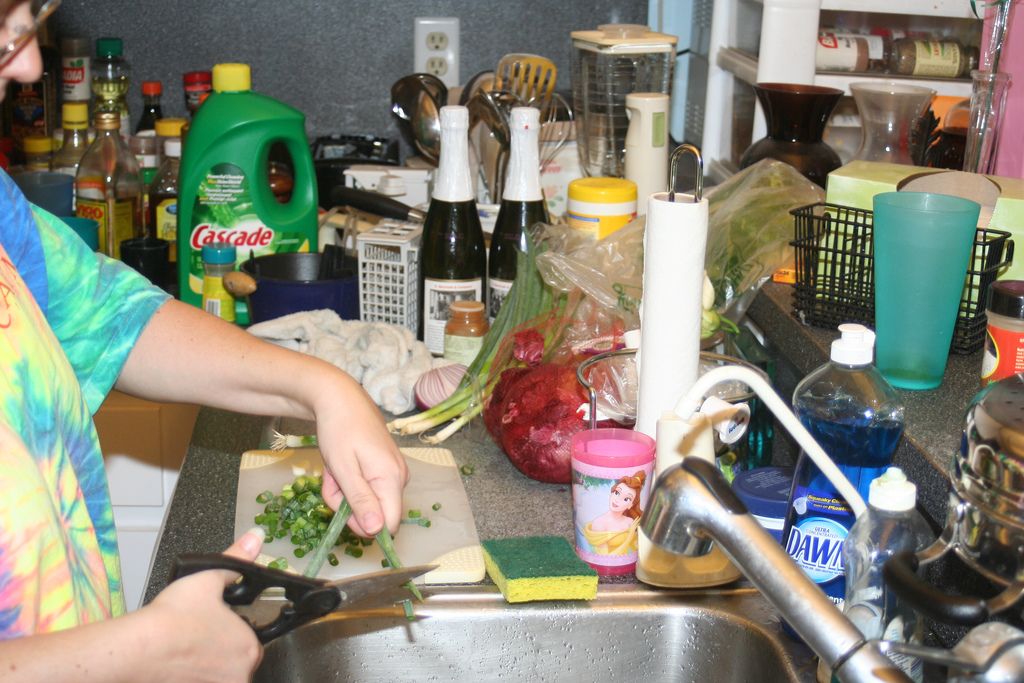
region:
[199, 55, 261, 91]
Lid on a bottle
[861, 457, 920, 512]
Lid on a bottle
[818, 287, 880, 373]
Lid on a bottle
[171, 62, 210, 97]
Lid on a bottle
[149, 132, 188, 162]
Lid on a bottle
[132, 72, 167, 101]
Lid on a bottle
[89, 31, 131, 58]
Lid on a bottle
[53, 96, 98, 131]
Lid on a bottle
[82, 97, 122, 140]
Lid on a bottle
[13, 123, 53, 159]
Lid on a bottle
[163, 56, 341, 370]
a green plastic container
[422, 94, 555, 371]
several wine bottles next to each other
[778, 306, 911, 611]
a bottle of dish washing liquid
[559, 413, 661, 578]
a pink cup with a princess design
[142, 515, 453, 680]
a hand holding a pair of kitchen sheers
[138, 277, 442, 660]
a person cutting some vegetables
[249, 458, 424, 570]
chopped vegetables on a chopping board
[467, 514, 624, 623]
a dish scrub pad with foam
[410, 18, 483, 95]
a wall outlet with 2 sockets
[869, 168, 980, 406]
a green plastic cup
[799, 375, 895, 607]
liquid is blue in color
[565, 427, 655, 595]
cup is pink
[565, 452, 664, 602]
cup has woman on it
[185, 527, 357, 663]
scissors handle is black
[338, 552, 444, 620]
scissor blades are silver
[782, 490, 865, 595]
logo on bottle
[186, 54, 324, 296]
bottle is green in color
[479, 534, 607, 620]
sponge is yellow and green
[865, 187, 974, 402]
cup is blue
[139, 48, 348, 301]
green container on the counter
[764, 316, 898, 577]
dishwasher on the sink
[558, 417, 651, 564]
cup on the counter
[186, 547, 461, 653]
woman holding black scissor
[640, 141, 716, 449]
paper towel on the counter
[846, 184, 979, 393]
green cup on the counter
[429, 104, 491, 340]
wine bottle on the counter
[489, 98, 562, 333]
wine bottle on the counter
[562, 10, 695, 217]
white blender on the counter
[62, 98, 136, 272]
oil on the counter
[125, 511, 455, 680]
hand holding a scissor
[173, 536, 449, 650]
the scissor is black and gray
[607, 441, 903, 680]
the faucet is color silver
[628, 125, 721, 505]
kitchen paper is white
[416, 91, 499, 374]
a bottle of wine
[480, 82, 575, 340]
a bottle of wine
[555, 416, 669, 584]
the cup is pink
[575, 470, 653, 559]
a fairy on a cup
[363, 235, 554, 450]
onions on a table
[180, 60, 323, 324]
Green bottle of dishwasher liquid.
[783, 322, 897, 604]
Blue bottle of dish washing soap on the sink.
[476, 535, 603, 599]
Green and yellow sponge on the sink.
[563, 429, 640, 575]
Pink cup with a princess on the sink.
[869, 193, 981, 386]
Large blue cup behind the sink.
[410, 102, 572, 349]
Two champagne bottles near a yellow canister.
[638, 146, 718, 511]
Paper towels on a metal pole.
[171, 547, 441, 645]
Scissors being used to cut.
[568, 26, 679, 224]
Blender with a tan top on the counter.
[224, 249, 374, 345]
Blue pot with a black inside.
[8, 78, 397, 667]
Person holding a pair of scissors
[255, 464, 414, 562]
Vegetables on a cutting board